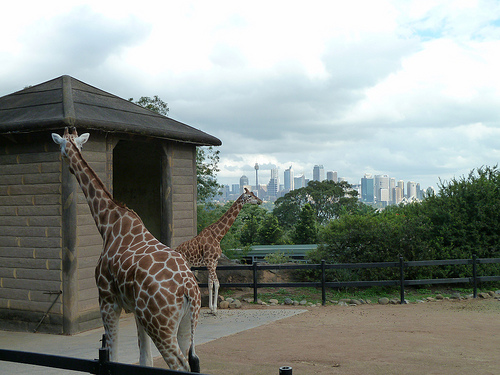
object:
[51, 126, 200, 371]
giraffe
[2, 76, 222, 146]
roof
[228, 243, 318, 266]
train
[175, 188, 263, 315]
animal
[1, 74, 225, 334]
house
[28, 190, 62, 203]
brick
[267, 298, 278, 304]
rock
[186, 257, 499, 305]
fence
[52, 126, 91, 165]
head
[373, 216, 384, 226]
leaves